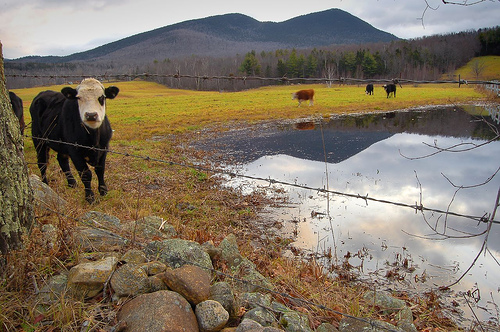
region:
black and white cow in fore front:
[28, 77, 115, 204]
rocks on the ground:
[56, 238, 266, 325]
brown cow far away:
[291, 89, 316, 103]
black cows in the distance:
[363, 81, 398, 98]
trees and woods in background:
[284, 42, 456, 78]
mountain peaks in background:
[211, 7, 393, 51]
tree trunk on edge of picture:
[1, 56, 42, 302]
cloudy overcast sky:
[361, 1, 495, 33]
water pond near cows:
[280, 130, 494, 277]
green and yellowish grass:
[120, 82, 291, 125]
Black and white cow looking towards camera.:
[29, 73, 121, 201]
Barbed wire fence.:
[8, 67, 498, 227]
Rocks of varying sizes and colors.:
[26, 170, 419, 327]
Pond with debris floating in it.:
[185, 107, 497, 328]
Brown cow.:
[290, 85, 315, 108]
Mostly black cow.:
[380, 78, 396, 99]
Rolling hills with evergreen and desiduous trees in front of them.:
[0, 5, 497, 90]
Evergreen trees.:
[245, 47, 396, 83]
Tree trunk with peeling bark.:
[0, 41, 36, 291]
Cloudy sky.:
[0, 1, 499, 63]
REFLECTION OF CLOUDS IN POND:
[326, 160, 469, 223]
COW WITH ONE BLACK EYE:
[68, 69, 126, 131]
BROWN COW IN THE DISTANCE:
[268, 72, 333, 119]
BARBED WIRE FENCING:
[251, 178, 471, 224]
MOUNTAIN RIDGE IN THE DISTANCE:
[190, 2, 285, 57]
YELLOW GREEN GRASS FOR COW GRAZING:
[124, 77, 332, 154]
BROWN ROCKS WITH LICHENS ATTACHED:
[148, 263, 231, 318]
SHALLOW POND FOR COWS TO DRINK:
[176, 86, 328, 196]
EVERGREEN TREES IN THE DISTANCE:
[224, 34, 365, 92]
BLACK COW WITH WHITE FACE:
[30, 66, 130, 177]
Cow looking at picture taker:
[16, 74, 131, 209]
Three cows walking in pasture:
[273, 71, 410, 109]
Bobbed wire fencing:
[130, 59, 493, 109]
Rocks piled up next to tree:
[36, 188, 299, 329]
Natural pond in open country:
[186, 106, 476, 271]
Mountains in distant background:
[28, 9, 460, 82]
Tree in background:
[237, 48, 477, 88]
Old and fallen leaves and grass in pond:
[156, 170, 478, 330]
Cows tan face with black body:
[57, 77, 120, 137]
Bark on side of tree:
[0, 44, 39, 284]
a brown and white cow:
[290, 83, 316, 112]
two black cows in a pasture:
[361, 77, 401, 99]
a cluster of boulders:
[60, 208, 320, 330]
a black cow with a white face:
[17, 71, 129, 201]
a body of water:
[198, 108, 498, 324]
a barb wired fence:
[12, 128, 499, 231]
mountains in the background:
[0, 3, 464, 75]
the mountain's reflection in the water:
[193, 101, 498, 168]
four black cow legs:
[31, 140, 113, 202]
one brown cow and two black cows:
[288, 81, 401, 110]